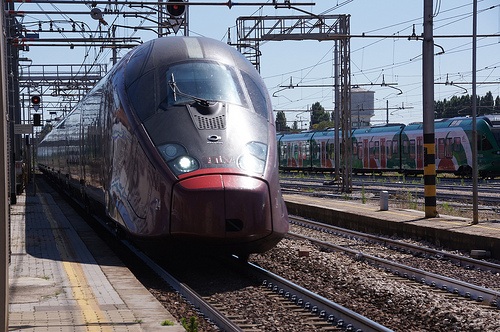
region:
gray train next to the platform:
[33, 33, 290, 261]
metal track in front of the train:
[123, 243, 393, 330]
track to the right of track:
[286, 213, 498, 313]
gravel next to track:
[267, 237, 498, 330]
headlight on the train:
[172, 154, 197, 171]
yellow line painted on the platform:
[33, 183, 113, 330]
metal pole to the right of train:
[420, 0, 441, 217]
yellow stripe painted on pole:
[423, 165, 435, 174]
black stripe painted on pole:
[421, 134, 435, 143]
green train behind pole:
[279, 113, 497, 178]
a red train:
[35, 33, 281, 249]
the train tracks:
[165, 243, 473, 323]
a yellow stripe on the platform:
[25, 187, 110, 322]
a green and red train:
[285, 121, 497, 187]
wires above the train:
[228, 10, 478, 105]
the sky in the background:
[190, 6, 228, 28]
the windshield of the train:
[163, 57, 266, 112]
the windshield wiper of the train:
[170, 70, 180, 95]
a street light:
[26, 88, 46, 108]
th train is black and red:
[92, 60, 329, 314]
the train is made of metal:
[97, 25, 300, 246]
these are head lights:
[152, 137, 273, 200]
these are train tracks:
[188, 272, 364, 325]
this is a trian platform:
[27, 185, 128, 314]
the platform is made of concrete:
[33, 220, 90, 285]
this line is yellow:
[30, 225, 101, 280]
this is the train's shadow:
[24, 169, 107, 270]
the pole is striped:
[387, 103, 472, 209]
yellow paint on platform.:
[86, 302, 100, 327]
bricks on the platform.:
[38, 314, 62, 326]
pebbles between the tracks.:
[371, 295, 397, 309]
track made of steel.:
[215, 312, 233, 329]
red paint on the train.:
[200, 180, 239, 186]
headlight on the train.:
[175, 157, 193, 173]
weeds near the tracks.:
[180, 313, 195, 327]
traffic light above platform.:
[32, 93, 42, 107]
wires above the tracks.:
[364, 57, 396, 74]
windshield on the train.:
[194, 73, 227, 88]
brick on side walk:
[108, 308, 121, 323]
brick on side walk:
[60, 313, 87, 325]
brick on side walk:
[34, 295, 54, 308]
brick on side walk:
[26, 281, 51, 294]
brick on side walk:
[53, 280, 69, 298]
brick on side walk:
[1, 305, 22, 323]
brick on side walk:
[38, 299, 50, 310]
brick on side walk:
[113, 300, 125, 317]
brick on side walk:
[81, 311, 108, 329]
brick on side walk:
[96, 295, 109, 310]